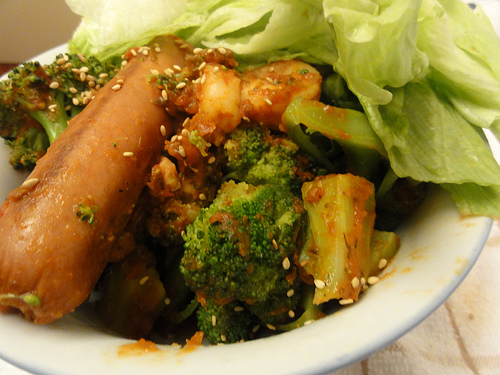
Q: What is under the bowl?
A: A cloth.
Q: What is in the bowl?
A: Meat and broccoli.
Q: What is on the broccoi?
A: Sauce and seeds.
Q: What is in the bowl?
A: Brococoli.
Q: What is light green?
A: Cabbage.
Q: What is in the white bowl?
A: Seseame seed begetables entre.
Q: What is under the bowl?
A: A white table cloth.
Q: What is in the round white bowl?
A: Vegetables.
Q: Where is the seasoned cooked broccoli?
A: Throughout bowl.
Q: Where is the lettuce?
A: Rim of the bowl.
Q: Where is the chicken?
A: In the dish.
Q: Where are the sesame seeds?
A: On the food.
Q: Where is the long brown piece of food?
A: In the dish.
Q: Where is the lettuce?
A: On the back of the dish.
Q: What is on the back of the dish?
A: Lettuce.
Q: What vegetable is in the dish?
A: Broccoli.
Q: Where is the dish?
A: On a table.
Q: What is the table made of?
A: Wood.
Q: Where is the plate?
A: Under the vegetables.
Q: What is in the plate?
A: Vegetables and potatoes.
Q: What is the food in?
A: A bowl.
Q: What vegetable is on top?
A: Lettuce.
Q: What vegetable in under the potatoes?
A: Broccoli.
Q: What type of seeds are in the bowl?
A: Sesame.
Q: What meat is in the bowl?
A: Hot dog.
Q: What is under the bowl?
A: Tablecloth.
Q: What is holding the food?
A: A white bowl.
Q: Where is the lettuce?
A: On top.